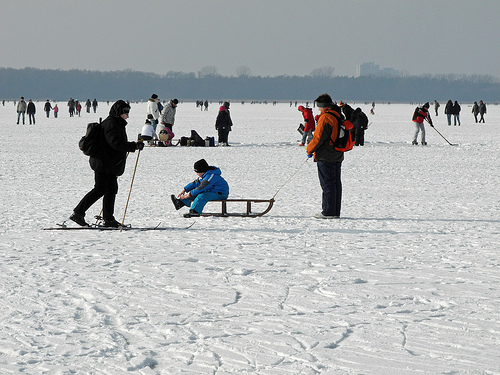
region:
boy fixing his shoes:
[159, 146, 232, 231]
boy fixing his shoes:
[162, 136, 270, 259]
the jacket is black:
[74, 116, 139, 187]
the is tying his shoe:
[157, 141, 308, 241]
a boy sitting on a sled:
[162, 141, 299, 243]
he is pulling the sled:
[291, 70, 381, 236]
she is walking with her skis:
[56, 51, 182, 254]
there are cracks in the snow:
[147, 272, 442, 374]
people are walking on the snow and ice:
[6, 79, 497, 241]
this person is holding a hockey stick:
[400, 84, 471, 170]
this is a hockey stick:
[424, 114, 469, 152]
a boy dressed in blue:
[156, 131, 242, 226]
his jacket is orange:
[302, 88, 363, 170]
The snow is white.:
[96, 302, 209, 372]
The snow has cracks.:
[149, 299, 271, 357]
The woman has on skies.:
[41, 194, 177, 244]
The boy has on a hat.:
[193, 156, 212, 177]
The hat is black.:
[193, 155, 215, 179]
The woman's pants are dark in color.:
[313, 154, 344, 223]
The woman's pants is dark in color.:
[69, 165, 125, 235]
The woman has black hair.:
[107, 97, 132, 121]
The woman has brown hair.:
[311, 92, 336, 110]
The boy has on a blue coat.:
[180, 157, 237, 197]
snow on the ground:
[127, 282, 324, 371]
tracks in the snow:
[50, 279, 119, 334]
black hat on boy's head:
[191, 158, 207, 171]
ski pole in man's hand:
[115, 127, 141, 230]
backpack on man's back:
[332, 113, 360, 152]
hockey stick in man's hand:
[423, 117, 464, 150]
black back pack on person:
[73, 120, 106, 160]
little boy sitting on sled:
[170, 155, 251, 225]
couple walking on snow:
[13, 94, 34, 126]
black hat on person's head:
[424, 98, 429, 107]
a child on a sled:
[166, 157, 281, 222]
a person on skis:
[38, 100, 185, 230]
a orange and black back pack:
[335, 117, 358, 159]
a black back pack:
[78, 119, 100, 161]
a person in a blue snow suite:
[180, 155, 232, 219]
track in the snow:
[219, 252, 462, 346]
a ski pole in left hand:
[118, 137, 150, 242]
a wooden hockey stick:
[426, 125, 458, 152]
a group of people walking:
[11, 89, 86, 129]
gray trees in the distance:
[13, 63, 490, 94]